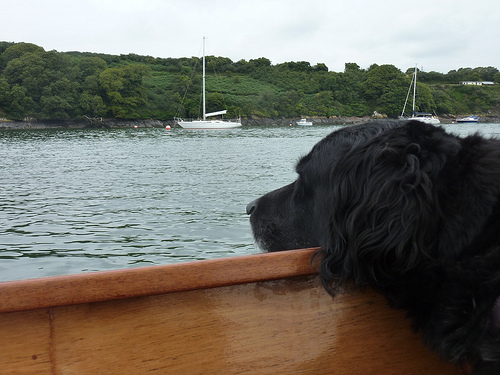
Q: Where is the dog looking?
A: At the water.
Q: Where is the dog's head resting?
A: On the ledge.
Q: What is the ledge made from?
A: Wood.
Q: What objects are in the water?
A: Boats.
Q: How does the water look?
A: Calm.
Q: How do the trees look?
A: Lush with green leaves.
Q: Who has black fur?
A: Dog.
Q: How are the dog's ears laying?
A: Flat against head.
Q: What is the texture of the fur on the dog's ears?
A: Wavy.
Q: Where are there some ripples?
A: In the water.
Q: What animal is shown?
A: Dog.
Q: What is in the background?
A: Trees.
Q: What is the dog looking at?
A: The water.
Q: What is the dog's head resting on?
A: A rail.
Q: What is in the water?
A: Boats.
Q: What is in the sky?
A: Clouds.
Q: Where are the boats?
A: On the water.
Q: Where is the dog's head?
A: On the wooden rail.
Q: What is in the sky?
A: Clouds.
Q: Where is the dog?
A: In a boat.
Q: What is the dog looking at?
A: The water.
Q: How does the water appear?
A: Calm.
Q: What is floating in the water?
A: Boats.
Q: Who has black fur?
A: A dog.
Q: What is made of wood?
A: The boat.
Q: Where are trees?
A: In the distance.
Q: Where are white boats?
A: On the water.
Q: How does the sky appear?
A: Cloudy.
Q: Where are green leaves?
A: On the trees.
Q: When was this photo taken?
A: Daytime.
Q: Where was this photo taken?
A: By a river.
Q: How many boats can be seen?
A: Four.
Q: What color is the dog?
A: Black.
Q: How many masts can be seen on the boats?
A: Two.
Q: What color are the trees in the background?
A: Green.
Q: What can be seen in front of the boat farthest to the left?
A: A buoy.